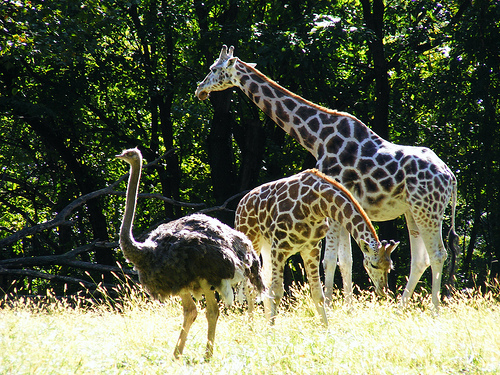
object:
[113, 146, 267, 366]
ostrich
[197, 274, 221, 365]
leg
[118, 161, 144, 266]
neck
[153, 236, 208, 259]
feathers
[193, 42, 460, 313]
giraffe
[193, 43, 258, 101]
head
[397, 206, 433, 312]
back leg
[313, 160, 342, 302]
front leg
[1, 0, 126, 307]
tree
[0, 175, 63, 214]
branch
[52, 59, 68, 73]
leaves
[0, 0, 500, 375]
plantation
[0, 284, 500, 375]
grass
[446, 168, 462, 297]
tail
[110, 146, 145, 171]
head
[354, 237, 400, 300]
head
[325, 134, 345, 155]
spot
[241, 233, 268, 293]
tail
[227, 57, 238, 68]
ear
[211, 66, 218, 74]
eye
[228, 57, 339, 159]
neck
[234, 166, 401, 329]
animal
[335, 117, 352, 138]
spots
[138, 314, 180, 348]
patch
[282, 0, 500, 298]
tree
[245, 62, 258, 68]
right ear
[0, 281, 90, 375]
part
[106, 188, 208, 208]
branches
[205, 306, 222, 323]
knee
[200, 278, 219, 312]
part